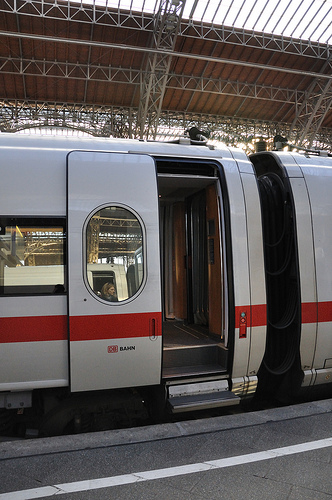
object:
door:
[154, 158, 236, 385]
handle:
[147, 311, 159, 343]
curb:
[1, 396, 331, 458]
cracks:
[190, 461, 296, 498]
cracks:
[0, 460, 67, 500]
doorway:
[149, 151, 235, 386]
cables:
[135, 0, 189, 139]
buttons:
[238, 300, 250, 344]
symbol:
[103, 341, 121, 355]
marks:
[170, 320, 202, 340]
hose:
[248, 150, 305, 391]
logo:
[105, 341, 137, 355]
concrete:
[0, 397, 332, 500]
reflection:
[87, 208, 142, 303]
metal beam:
[132, 52, 171, 140]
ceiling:
[0, 0, 332, 123]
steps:
[161, 348, 236, 411]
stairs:
[159, 344, 241, 415]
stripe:
[0, 295, 332, 349]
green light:
[241, 311, 246, 318]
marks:
[174, 420, 189, 438]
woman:
[87, 265, 129, 317]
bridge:
[3, 0, 332, 138]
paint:
[150, 420, 331, 492]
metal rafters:
[0, 98, 306, 138]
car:
[0, 122, 332, 435]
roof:
[0, 1, 331, 133]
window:
[78, 201, 148, 307]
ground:
[0, 399, 332, 500]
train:
[0, 135, 268, 419]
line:
[0, 435, 332, 500]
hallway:
[159, 175, 230, 373]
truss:
[0, 0, 332, 62]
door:
[64, 153, 163, 397]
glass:
[82, 201, 147, 303]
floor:
[166, 317, 229, 382]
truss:
[0, 50, 145, 89]